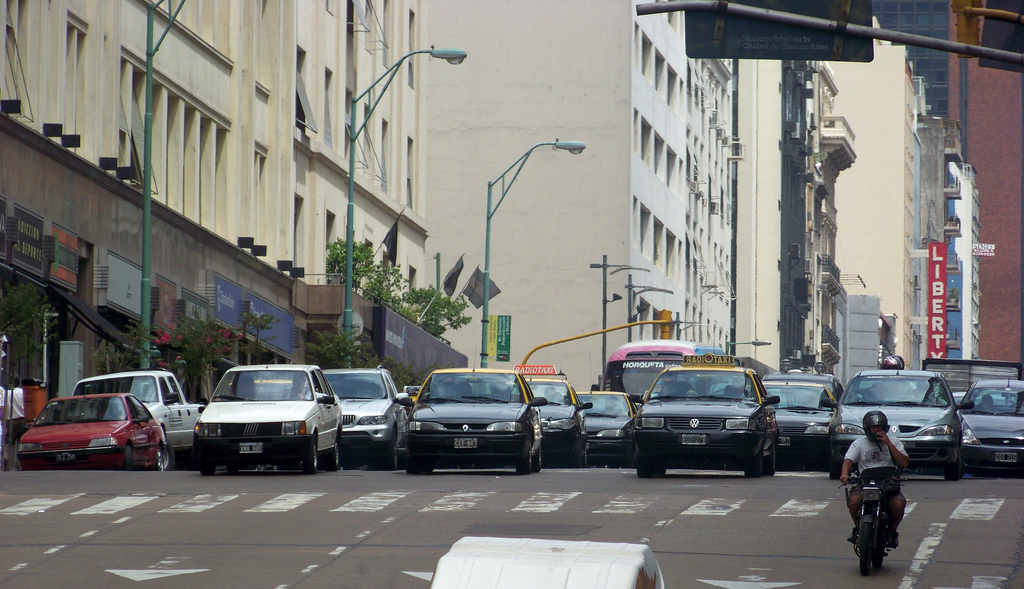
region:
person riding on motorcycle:
[822, 405, 911, 583]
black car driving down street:
[395, 358, 552, 477]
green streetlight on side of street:
[325, 34, 472, 364]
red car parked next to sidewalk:
[8, 379, 177, 484]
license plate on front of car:
[672, 423, 715, 453]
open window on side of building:
[284, 35, 324, 144]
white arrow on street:
[94, 540, 222, 586]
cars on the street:
[0, 307, 1023, 523]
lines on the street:
[19, 450, 1019, 584]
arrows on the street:
[82, 529, 242, 586]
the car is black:
[609, 352, 786, 482]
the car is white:
[192, 354, 374, 475]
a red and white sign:
[903, 222, 962, 387]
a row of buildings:
[8, 13, 992, 410]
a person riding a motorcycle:
[842, 402, 913, 549]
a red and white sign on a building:
[929, 238, 956, 363]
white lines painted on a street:
[20, 482, 792, 530]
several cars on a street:
[40, 359, 1020, 461]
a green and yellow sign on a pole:
[478, 307, 513, 355]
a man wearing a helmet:
[864, 409, 904, 435]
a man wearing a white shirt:
[852, 431, 904, 469]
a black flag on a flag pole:
[368, 206, 407, 276]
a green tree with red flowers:
[158, 311, 226, 363]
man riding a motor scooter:
[843, 401, 917, 578]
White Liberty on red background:
[928, 225, 948, 365]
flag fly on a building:
[356, 209, 502, 317]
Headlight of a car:
[482, 413, 524, 439]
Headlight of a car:
[404, 413, 456, 439]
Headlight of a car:
[724, 407, 756, 437]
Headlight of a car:
[87, 433, 117, 453]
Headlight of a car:
[12, 439, 45, 458]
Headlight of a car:
[957, 426, 978, 450]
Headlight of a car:
[800, 417, 833, 440]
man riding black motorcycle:
[842, 403, 926, 572]